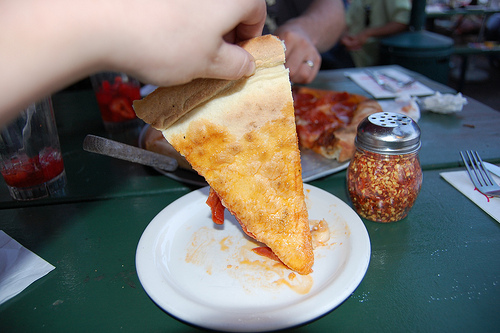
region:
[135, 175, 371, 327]
White plate sitting on the table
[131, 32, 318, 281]
Slice of pizza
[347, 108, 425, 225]
Shaker with hot pepper seasoning in it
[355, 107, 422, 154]
Silver top of pepper shaker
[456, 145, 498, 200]
Head of fork on a white napkin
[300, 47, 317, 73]
Ring on person's left hand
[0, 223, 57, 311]
White napkin lying on the table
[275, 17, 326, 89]
Left hand of person sitting at the table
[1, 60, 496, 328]
Blue tabletop with pizza on it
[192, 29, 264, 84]
Right thumb of person eating pizza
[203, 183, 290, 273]
Toppings sliding off the slice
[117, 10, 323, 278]
Holding a slice of pizza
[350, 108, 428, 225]
Bottle of hot pepper flakes on the table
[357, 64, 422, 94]
Silverware setting on the table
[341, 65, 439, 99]
Silverware sitting on a white napkin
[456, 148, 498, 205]
Four pronged fork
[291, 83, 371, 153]
Pepperoni, sauce and cheese on this pizza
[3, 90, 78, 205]
Glass of beverage almost gone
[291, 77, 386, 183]
Remaining slices on the tray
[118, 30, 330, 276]
Holding the slice almost upside down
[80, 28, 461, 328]
a slice of pizza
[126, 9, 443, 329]
a hand holding a slice of pizza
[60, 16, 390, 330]
the bottom of a pizza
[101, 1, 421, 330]
bottom of a slice of pizza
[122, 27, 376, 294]
a cooked pizza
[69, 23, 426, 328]
a cooked slice of pizza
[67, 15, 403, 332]
a baked slice of pizza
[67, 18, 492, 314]
a pizza on a plate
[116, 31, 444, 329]
a pizza above a plate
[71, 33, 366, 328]
a slice of pizza being held up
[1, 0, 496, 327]
A restaurant scene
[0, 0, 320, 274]
A hand is holding a slice of pizza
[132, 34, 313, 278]
The pizza slice has cheese on it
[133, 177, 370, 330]
A white plate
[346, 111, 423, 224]
A shake top container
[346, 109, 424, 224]
The shaker has red pepper flakes in it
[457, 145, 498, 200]
A fork is laying on the table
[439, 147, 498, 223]
A paper napkin is under the fork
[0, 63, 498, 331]
The table is green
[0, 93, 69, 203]
A drinking glass is on the table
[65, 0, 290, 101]
a hand grasping a slice of pizza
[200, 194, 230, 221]
red tomato on the pizza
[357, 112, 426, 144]
a sliver perforated top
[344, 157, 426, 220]
a glass jar of red pepper flakes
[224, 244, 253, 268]
tomato juice on the saucer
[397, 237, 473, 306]
white salt sprinkles the table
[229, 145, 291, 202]
thick yellow cheese on the pizza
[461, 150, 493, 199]
metal fork prongs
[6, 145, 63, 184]
red liquid in glass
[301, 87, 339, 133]
pepperoni slices on top of a pizza